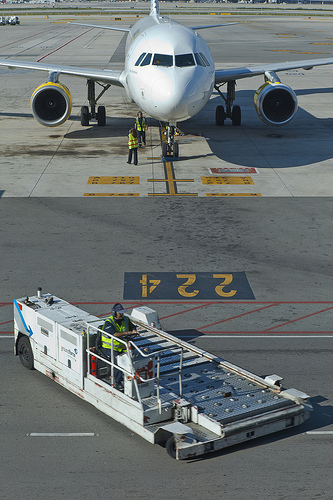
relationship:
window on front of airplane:
[173, 51, 196, 69] [0, 1, 332, 161]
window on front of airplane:
[151, 51, 173, 69] [0, 1, 332, 161]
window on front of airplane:
[140, 53, 149, 64] [0, 1, 332, 161]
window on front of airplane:
[195, 52, 205, 67] [0, 1, 332, 161]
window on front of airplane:
[135, 52, 144, 63] [0, 1, 332, 161]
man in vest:
[120, 95, 159, 145] [121, 133, 146, 152]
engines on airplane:
[253, 79, 300, 125] [0, 1, 332, 161]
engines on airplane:
[28, 77, 74, 128] [0, 1, 332, 161]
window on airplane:
[151, 51, 171, 67] [0, 1, 332, 161]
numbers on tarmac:
[115, 268, 247, 296] [80, 209, 271, 273]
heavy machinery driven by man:
[12, 283, 316, 455] [103, 298, 137, 394]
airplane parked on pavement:
[0, 1, 332, 161] [0, 0, 332, 499]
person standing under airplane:
[124, 122, 139, 165] [0, 1, 332, 161]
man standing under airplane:
[132, 109, 148, 148] [0, 1, 332, 161]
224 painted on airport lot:
[129, 265, 241, 306] [0, 4, 333, 498]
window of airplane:
[133, 52, 144, 64] [0, 1, 332, 161]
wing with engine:
[0, 60, 124, 89] [25, 73, 76, 132]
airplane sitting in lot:
[0, 1, 332, 161] [266, 231, 312, 301]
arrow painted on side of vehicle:
[10, 303, 36, 342] [5, 283, 318, 464]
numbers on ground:
[207, 172, 255, 184] [0, 195, 332, 497]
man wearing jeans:
[100, 304, 137, 391] [101, 346, 122, 389]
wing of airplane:
[214, 57, 331, 80] [0, 1, 332, 161]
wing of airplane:
[0, 56, 124, 85] [0, 1, 332, 161]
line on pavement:
[25, 432, 100, 439] [1, 376, 94, 499]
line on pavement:
[302, 430, 332, 437] [1, 376, 94, 499]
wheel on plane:
[149, 136, 195, 170] [0, 1, 333, 159]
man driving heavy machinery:
[98, 297, 139, 394] [12, 283, 313, 463]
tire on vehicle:
[13, 333, 38, 370] [5, 283, 318, 464]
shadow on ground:
[186, 82, 332, 166] [0, 118, 332, 336]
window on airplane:
[129, 48, 211, 72] [0, 1, 332, 161]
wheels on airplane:
[213, 103, 242, 124] [1, 1, 332, 128]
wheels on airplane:
[79, 105, 106, 126] [1, 1, 332, 128]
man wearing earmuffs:
[100, 304, 137, 391] [112, 303, 117, 320]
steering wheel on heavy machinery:
[121, 334, 138, 341] [12, 283, 313, 463]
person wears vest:
[128, 133, 143, 158] [126, 133, 139, 150]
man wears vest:
[132, 109, 148, 148] [134, 115, 144, 130]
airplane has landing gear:
[0, 1, 332, 161] [213, 80, 242, 126]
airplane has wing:
[1, 1, 332, 128] [3, 57, 118, 86]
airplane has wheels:
[0, 1, 332, 161] [79, 105, 91, 126]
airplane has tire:
[0, 1, 332, 161] [96, 104, 106, 124]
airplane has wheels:
[0, 1, 332, 161] [213, 103, 226, 128]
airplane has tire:
[0, 1, 332, 161] [231, 104, 240, 125]